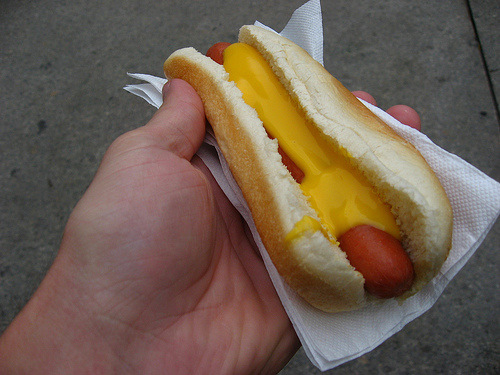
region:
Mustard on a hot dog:
[219, 37, 407, 244]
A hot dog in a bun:
[161, 16, 456, 318]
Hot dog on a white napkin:
[120, 2, 498, 373]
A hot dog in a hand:
[8, 5, 449, 371]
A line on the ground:
[460, 3, 499, 123]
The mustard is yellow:
[219, 38, 407, 247]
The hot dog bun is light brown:
[161, 18, 459, 318]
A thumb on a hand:
[132, 66, 212, 166]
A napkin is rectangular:
[121, 2, 498, 373]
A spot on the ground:
[29, 110, 50, 141]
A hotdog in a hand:
[175, 15, 442, 318]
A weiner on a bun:
[170, 11, 450, 311]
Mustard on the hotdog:
[220, 45, 380, 247]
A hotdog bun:
[386, 138, 449, 200]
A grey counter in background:
[26, 25, 98, 115]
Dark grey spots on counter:
[26, 77, 63, 167]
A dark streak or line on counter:
[458, 7, 498, 104]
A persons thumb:
[119, 60, 197, 162]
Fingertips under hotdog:
[356, 80, 419, 127]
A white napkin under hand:
[445, 148, 487, 250]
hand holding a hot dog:
[55, 7, 452, 359]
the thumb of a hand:
[118, 73, 208, 186]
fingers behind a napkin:
[349, 80, 429, 147]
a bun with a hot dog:
[156, 13, 458, 326]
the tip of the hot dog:
[343, 231, 419, 301]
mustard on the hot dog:
[153, 9, 458, 322]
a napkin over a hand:
[117, 0, 499, 367]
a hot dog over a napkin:
[116, 0, 498, 372]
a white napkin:
[117, 2, 497, 370]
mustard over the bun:
[278, 202, 327, 255]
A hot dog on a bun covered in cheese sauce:
[162, 11, 457, 307]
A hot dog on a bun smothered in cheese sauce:
[168, 13, 457, 310]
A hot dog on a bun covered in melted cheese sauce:
[163, 16, 477, 312]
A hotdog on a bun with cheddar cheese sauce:
[158, 17, 463, 306]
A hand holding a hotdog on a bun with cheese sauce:
[68, 20, 480, 355]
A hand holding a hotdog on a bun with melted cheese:
[83, 21, 482, 361]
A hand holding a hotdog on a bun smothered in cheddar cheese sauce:
[96, 19, 456, 363]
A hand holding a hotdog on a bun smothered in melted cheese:
[101, 19, 497, 340]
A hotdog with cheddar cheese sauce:
[163, 14, 463, 319]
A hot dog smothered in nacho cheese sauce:
[163, 12, 445, 308]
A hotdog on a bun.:
[159, 23, 454, 318]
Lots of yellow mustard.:
[218, 41, 400, 247]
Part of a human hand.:
[0, 76, 304, 373]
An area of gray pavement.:
[0, 0, 312, 332]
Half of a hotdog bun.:
[161, 46, 368, 315]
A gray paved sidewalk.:
[321, 0, 499, 186]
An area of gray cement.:
[278, 218, 498, 373]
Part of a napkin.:
[253, 0, 338, 71]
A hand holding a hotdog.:
[0, 19, 452, 373]